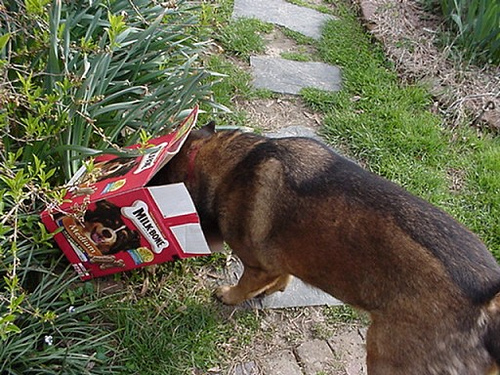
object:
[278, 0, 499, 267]
grass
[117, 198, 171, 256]
bone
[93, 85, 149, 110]
stems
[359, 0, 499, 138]
grass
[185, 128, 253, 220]
neck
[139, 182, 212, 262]
flap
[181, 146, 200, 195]
collar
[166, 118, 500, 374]
dog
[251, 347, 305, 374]
stones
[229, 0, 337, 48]
tile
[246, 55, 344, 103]
tile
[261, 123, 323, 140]
tile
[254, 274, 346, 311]
tile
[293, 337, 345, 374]
tile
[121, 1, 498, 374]
ground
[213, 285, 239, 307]
paws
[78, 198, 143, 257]
head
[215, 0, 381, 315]
path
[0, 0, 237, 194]
plants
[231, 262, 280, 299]
leg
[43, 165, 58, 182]
leaves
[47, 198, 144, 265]
dog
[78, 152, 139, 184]
dog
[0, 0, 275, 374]
grass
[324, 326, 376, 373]
brick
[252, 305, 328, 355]
mud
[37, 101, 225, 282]
red box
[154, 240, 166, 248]
lettering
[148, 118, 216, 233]
dog's head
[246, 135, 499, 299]
back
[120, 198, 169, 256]
logo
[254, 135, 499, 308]
streak